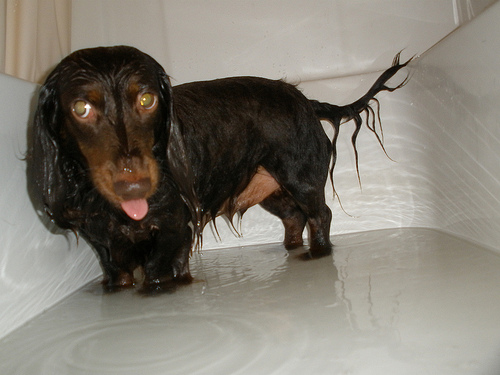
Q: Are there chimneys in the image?
A: No, there are no chimneys.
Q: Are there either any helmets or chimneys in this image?
A: No, there are no chimneys or helmets.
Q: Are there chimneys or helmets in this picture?
A: No, there are no chimneys or helmets.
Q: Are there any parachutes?
A: No, there are no parachutes.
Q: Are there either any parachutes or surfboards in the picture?
A: No, there are no parachutes or surfboards.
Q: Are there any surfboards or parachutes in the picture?
A: No, there are no parachutes or surfboards.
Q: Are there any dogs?
A: Yes, there is a dog.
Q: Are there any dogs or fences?
A: Yes, there is a dog.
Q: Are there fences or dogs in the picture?
A: Yes, there is a dog.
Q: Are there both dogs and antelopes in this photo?
A: No, there is a dog but no antelopes.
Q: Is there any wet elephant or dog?
A: Yes, there is a wet dog.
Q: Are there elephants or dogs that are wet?
A: Yes, the dog is wet.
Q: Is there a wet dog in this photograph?
A: Yes, there is a wet dog.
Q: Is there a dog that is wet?
A: Yes, there is a dog that is wet.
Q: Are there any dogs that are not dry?
A: Yes, there is a wet dog.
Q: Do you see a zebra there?
A: No, there are no zebras.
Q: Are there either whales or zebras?
A: No, there are no zebras or whales.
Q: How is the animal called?
A: The animal is a dog.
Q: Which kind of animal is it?
A: The animal is a dog.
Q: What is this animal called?
A: That is a dog.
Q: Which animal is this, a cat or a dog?
A: That is a dog.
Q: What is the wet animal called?
A: The animal is a dog.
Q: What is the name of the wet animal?
A: The animal is a dog.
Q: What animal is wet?
A: The animal is a dog.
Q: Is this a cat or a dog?
A: This is a dog.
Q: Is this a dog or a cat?
A: This is a dog.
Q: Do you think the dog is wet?
A: Yes, the dog is wet.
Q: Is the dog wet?
A: Yes, the dog is wet.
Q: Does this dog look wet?
A: Yes, the dog is wet.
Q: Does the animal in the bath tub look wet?
A: Yes, the dog is wet.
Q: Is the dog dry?
A: No, the dog is wet.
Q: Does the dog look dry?
A: No, the dog is wet.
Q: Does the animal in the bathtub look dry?
A: No, the dog is wet.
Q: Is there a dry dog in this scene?
A: No, there is a dog but it is wet.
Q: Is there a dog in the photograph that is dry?
A: No, there is a dog but it is wet.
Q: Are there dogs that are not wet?
A: No, there is a dog but it is wet.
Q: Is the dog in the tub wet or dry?
A: The dog is wet.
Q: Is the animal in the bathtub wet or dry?
A: The dog is wet.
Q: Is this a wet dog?
A: Yes, this is a wet dog.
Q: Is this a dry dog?
A: No, this is a wet dog.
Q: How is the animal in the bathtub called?
A: The animal is a dog.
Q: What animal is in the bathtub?
A: The animal is a dog.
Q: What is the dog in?
A: The dog is in the bath tub.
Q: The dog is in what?
A: The dog is in the bath tub.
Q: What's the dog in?
A: The dog is in the bath tub.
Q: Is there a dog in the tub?
A: Yes, there is a dog in the tub.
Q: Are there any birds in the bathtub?
A: No, there is a dog in the bathtub.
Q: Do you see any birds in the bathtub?
A: No, there is a dog in the bathtub.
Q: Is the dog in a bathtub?
A: Yes, the dog is in a bathtub.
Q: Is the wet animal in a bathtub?
A: Yes, the dog is in a bathtub.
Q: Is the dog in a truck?
A: No, the dog is in a bathtub.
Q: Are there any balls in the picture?
A: No, there are no balls.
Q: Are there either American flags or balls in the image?
A: No, there are no balls or American flags.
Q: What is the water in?
A: The water is in the tub.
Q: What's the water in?
A: The water is in the tub.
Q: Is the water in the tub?
A: Yes, the water is in the tub.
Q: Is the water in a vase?
A: No, the water is in the tub.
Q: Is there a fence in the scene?
A: No, there are no fences.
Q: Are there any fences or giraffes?
A: No, there are no fences or giraffes.